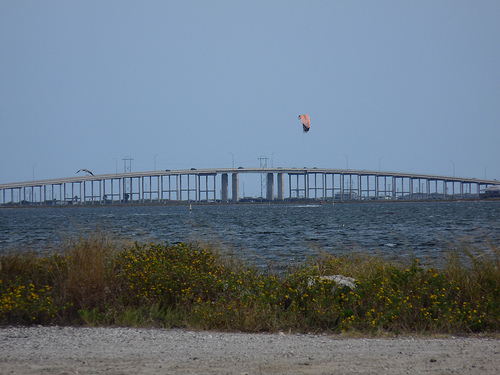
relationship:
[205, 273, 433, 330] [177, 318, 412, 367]
weeds on gruond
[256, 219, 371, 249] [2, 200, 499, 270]
ripple in water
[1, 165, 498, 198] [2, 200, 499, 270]
bridge above water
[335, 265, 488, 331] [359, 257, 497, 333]
flowers in plant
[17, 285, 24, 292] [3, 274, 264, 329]
flower in plant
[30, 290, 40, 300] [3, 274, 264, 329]
flower in plant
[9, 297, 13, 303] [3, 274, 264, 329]
flower in plant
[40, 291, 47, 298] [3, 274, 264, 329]
flower in plant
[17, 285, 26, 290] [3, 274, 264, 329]
flower in plant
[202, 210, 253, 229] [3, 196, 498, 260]
ripples in ocean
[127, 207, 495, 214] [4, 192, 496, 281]
ripple in water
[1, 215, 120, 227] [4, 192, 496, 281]
ripple in water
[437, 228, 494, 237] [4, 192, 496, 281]
ripple in water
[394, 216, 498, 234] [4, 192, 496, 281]
ripple in water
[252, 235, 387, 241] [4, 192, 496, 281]
ripple in water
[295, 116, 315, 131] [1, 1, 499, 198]
parasail in sky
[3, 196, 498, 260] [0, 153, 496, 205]
ocean next to bridge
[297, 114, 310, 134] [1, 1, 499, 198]
parasail in sky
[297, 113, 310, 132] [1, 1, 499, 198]
kite flying in sky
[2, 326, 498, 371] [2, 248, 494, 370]
sand on top of ground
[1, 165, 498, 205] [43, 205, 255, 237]
bridge above water